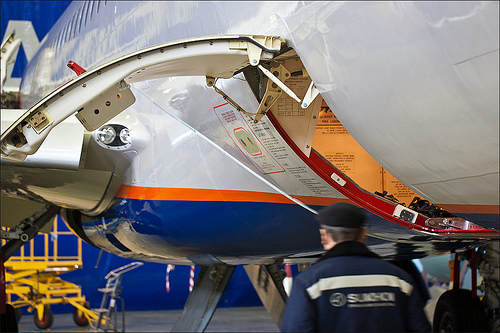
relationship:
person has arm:
[245, 178, 465, 331] [278, 275, 318, 331]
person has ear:
[245, 178, 465, 331] [319, 226, 329, 246]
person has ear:
[245, 178, 465, 331] [358, 223, 368, 244]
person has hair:
[245, 178, 465, 331] [308, 203, 368, 243]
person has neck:
[245, 178, 465, 331] [320, 237, 371, 253]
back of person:
[318, 273, 395, 327] [280, 194, 431, 324]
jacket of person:
[287, 251, 430, 331] [245, 178, 465, 331]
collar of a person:
[316, 241, 378, 260] [275, 200, 437, 325]